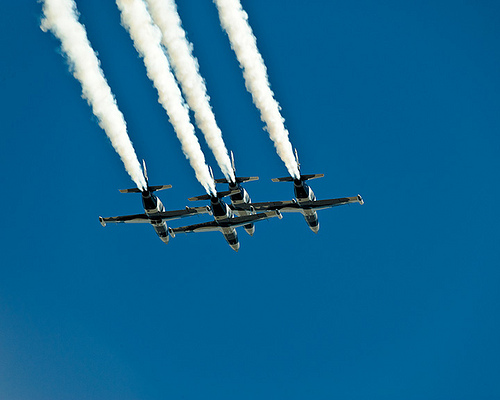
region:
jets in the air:
[85, 178, 375, 235]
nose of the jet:
[228, 242, 241, 256]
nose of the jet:
[158, 235, 172, 247]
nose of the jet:
[244, 227, 256, 237]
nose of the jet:
[306, 223, 326, 235]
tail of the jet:
[118, 183, 170, 193]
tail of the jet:
[196, 187, 228, 200]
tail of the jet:
[216, 173, 260, 183]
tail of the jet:
[271, 166, 315, 188]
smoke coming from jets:
[31, 23, 312, 171]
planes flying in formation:
[70, 10, 355, 261]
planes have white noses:
[230, 233, 247, 251]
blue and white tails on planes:
[222, 160, 257, 187]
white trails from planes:
[85, 1, 285, 157]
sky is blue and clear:
[307, 43, 448, 128]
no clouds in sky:
[358, 5, 471, 140]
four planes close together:
[119, 155, 353, 255]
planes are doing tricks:
[108, 136, 383, 297]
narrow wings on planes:
[112, 200, 212, 235]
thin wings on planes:
[112, 192, 181, 234]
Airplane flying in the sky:
[98, 181, 209, 243]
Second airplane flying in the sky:
[188, 187, 280, 257]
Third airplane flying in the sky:
[217, 171, 271, 236]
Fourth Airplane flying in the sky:
[268, 172, 365, 239]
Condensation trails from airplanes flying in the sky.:
[39, 1, 305, 172]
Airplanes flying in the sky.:
[96, 169, 368, 251]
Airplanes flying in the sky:
[93, 171, 364, 247]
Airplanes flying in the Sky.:
[96, 171, 366, 252]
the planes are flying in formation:
[65, 140, 396, 265]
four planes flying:
[49, 138, 418, 296]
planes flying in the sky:
[67, 109, 398, 274]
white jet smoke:
[40, 5, 352, 195]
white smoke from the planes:
[47, 0, 309, 180]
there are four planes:
[48, 140, 452, 267]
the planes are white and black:
[65, 121, 380, 322]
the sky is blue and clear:
[24, 137, 412, 393]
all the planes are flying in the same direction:
[49, 112, 401, 264]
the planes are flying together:
[67, 139, 409, 273]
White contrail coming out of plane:
[212, 0, 301, 179]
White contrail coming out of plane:
[140, 0, 235, 179]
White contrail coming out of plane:
[38, 0, 148, 192]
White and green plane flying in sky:
[260, 167, 363, 234]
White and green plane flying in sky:
[187, 175, 282, 237]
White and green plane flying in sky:
[94, 180, 208, 241]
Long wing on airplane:
[312, 191, 369, 211]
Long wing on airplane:
[231, 207, 282, 232]